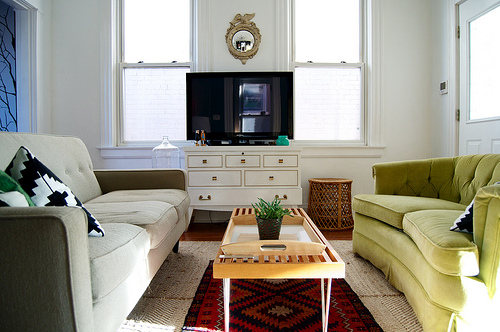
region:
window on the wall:
[115, 6, 190, 136]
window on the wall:
[290, 4, 362, 134]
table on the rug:
[209, 200, 350, 329]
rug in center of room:
[193, 246, 349, 330]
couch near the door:
[346, 142, 488, 315]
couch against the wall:
[1, 120, 195, 315]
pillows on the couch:
[0, 148, 111, 233]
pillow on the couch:
[462, 185, 483, 253]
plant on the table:
[243, 196, 290, 238]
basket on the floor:
[295, 172, 360, 232]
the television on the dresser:
[177, 65, 304, 142]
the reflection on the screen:
[228, 81, 278, 119]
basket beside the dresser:
[301, 170, 366, 236]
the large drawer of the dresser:
[193, 186, 304, 208]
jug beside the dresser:
[135, 130, 191, 172]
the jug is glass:
[144, 136, 183, 167]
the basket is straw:
[298, 171, 353, 233]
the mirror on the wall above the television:
[214, 7, 270, 64]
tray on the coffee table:
[221, 191, 345, 285]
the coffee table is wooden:
[202, 198, 332, 329]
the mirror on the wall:
[220, 8, 268, 66]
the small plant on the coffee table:
[246, 193, 290, 242]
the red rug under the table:
[182, 280, 378, 328]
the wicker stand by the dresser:
[305, 172, 354, 234]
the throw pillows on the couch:
[0, 145, 106, 247]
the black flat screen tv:
[182, 65, 297, 147]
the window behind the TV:
[289, 0, 371, 147]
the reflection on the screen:
[223, 78, 279, 134]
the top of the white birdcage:
[149, 135, 183, 166]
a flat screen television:
[183, 69, 295, 143]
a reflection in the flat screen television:
[225, 75, 283, 137]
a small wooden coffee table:
[210, 202, 345, 330]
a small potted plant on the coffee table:
[250, 193, 295, 240]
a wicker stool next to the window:
[307, 173, 356, 232]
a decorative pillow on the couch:
[4, 142, 109, 237]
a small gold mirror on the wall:
[224, 8, 263, 68]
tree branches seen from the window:
[0, 5, 18, 132]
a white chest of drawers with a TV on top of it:
[182, 142, 304, 228]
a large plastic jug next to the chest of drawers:
[151, 135, 181, 171]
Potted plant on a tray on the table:
[250, 194, 285, 239]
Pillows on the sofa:
[0, 144, 106, 240]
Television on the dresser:
[185, 72, 295, 145]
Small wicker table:
[309, 177, 352, 232]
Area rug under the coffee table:
[182, 259, 380, 329]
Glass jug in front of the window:
[149, 135, 181, 170]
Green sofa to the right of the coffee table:
[353, 151, 498, 324]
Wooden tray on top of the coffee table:
[221, 210, 325, 257]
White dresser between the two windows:
[185, 144, 303, 227]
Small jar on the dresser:
[272, 132, 293, 147]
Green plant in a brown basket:
[252, 197, 291, 240]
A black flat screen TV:
[183, 69, 298, 144]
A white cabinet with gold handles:
[184, 144, 305, 211]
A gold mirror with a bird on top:
[222, 8, 262, 65]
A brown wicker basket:
[307, 175, 357, 233]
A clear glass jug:
[150, 134, 183, 170]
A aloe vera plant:
[252, 195, 291, 242]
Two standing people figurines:
[192, 127, 207, 144]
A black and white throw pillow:
[5, 143, 106, 238]